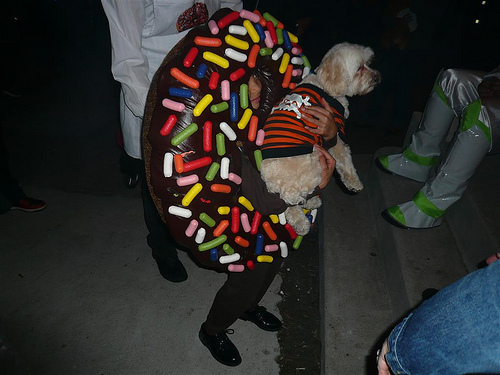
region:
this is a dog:
[271, 27, 372, 229]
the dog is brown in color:
[330, 48, 346, 93]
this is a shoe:
[218, 345, 248, 374]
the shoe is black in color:
[230, 350, 238, 359]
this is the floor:
[35, 235, 119, 357]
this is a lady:
[176, 33, 292, 293]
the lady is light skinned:
[309, 110, 339, 144]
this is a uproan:
[114, 18, 159, 61]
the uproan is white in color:
[113, 31, 140, 77]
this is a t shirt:
[285, 103, 301, 145]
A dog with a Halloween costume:
[255, 26, 390, 208]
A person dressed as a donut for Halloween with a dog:
[136, 0, 384, 373]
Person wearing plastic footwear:
[378, 66, 498, 248]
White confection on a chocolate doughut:
[160, 149, 174, 181]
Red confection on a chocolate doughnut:
[176, 44, 199, 68]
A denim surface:
[422, 309, 493, 367]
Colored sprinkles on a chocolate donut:
[165, 146, 242, 231]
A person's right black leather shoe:
[193, 303, 245, 370]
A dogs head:
[310, 37, 397, 104]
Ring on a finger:
[357, 331, 392, 373]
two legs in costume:
[374, 66, 496, 231]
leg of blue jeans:
[387, 264, 498, 372]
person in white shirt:
[102, 2, 242, 155]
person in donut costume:
[142, 8, 322, 275]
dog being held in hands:
[261, 42, 382, 206]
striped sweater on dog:
[262, 84, 346, 160]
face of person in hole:
[242, 70, 264, 111]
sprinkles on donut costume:
[143, 7, 326, 274]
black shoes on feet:
[199, 309, 282, 365]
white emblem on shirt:
[269, 93, 308, 120]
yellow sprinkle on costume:
[189, 99, 208, 114]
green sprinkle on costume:
[198, 216, 216, 226]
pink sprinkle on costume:
[188, 218, 198, 234]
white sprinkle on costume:
[162, 154, 174, 172]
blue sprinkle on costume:
[255, 232, 271, 254]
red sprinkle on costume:
[229, 201, 241, 226]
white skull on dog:
[276, 94, 307, 113]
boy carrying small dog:
[262, 97, 376, 212]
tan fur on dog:
[260, 157, 301, 189]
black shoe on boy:
[193, 305, 250, 372]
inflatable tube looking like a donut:
[155, 10, 318, 274]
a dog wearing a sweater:
[272, 39, 382, 205]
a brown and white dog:
[270, 33, 381, 205]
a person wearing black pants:
[205, 271, 282, 311]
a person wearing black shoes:
[197, 298, 279, 357]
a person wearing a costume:
[402, 58, 492, 229]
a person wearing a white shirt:
[97, 2, 232, 126]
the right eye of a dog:
[355, 58, 364, 75]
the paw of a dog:
[337, 164, 367, 194]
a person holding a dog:
[163, 20, 377, 241]